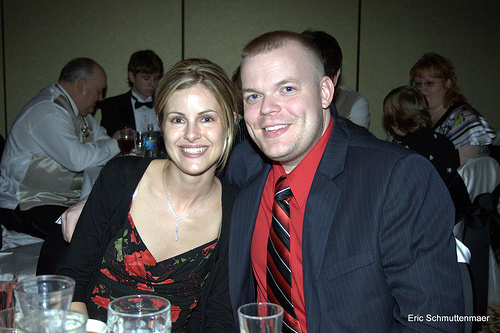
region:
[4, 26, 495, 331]
people at a banquet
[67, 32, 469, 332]
a man and woman in dress clothes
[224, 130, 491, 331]
a man wearing a suit and tie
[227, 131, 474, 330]
a striped suit jacket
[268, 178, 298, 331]
a black and red striped tie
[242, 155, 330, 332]
a red dress shirt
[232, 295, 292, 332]
the top of a champagne flute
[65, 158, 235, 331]
a woman wearing a red flowered dress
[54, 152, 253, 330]
a woman wearing a black sweater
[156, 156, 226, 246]
a woman wearing a necklace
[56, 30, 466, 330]
Couple smiling into camera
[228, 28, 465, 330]
Man wearing a black pinstripe suit jacket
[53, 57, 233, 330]
Blonde woman wearing black and red floral print dress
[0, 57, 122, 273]
Large man wearing a beige and white vest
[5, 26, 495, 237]
Table of people in the background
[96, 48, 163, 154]
Boy wearing a black tux and bowtie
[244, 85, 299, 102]
Pair of blue eyes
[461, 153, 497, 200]
Top of chair with white silk cover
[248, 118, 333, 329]
Red shirt with red, black and white striped tie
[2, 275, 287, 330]
Tops of different sized glasses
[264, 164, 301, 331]
red black and grey tie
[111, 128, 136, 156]
Glass of red wine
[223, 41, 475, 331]
Man with blue eyes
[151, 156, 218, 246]
Diamond tear drop necklace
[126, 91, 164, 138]
Black bow tie over a white dress shirt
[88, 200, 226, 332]
floral pattern woman's dress shirt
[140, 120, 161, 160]
bottle of water sitting on a table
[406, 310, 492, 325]
Name of the photographer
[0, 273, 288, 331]
six glasses sitting in front of two people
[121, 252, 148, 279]
Red rose on a blouse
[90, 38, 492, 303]
Man and woman sitting together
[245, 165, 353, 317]
Man is wearing a tie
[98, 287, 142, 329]
Glass sitting on the table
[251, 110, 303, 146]
Man is smiling at the camera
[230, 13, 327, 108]
Man has short hair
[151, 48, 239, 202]
The woman has her hair up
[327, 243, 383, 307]
Pocket on front of the jacket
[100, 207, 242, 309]
Flowers on the front of the shirt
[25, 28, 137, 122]
Man is going bald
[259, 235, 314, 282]
The tie is striped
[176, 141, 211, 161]
the lady is smiling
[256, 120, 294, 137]
the man is smiling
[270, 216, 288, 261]
the tie has stripes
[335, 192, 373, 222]
the jacket is gray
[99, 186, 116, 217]
the jacket is black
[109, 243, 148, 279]
the dress has red flowers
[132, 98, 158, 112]
he is wearing a bow tie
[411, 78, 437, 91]
she's wearing glasses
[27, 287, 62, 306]
the cup is clear